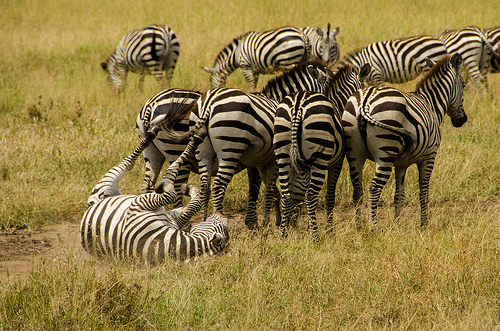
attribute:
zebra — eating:
[106, 20, 182, 90]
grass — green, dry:
[0, 30, 84, 207]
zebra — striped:
[343, 57, 468, 230]